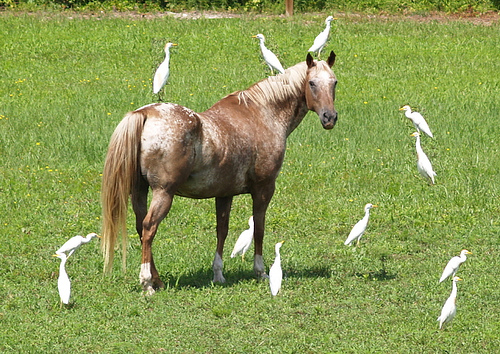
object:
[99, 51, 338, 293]
horse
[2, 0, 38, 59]
grass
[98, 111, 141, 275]
tail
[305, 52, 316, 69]
ear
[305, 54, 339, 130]
head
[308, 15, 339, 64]
bird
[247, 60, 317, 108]
mane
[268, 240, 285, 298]
bird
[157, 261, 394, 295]
grass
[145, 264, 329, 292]
shadow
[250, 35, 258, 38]
beak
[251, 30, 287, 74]
bird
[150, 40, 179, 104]
bird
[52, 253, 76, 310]
bird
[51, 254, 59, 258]
beak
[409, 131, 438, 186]
bird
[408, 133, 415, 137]
beak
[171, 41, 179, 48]
beak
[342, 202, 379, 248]
bird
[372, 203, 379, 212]
beak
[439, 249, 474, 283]
bird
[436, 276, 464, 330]
bird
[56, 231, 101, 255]
bird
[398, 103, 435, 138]
bird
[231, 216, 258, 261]
bird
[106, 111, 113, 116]
flower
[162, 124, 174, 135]
patches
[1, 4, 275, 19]
path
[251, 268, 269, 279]
hoof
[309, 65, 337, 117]
face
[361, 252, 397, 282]
shadow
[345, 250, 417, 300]
ground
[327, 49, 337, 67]
ear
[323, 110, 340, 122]
nose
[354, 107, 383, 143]
green grass